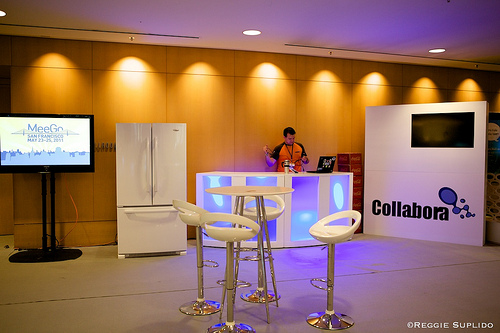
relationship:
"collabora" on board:
[368, 195, 453, 224] [360, 99, 489, 250]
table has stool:
[198, 180, 304, 328] [304, 210, 361, 329]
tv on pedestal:
[2, 109, 97, 176] [9, 169, 84, 265]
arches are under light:
[9, 36, 470, 109] [241, 28, 262, 39]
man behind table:
[258, 123, 313, 175] [198, 180, 304, 328]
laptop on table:
[309, 152, 338, 175] [198, 180, 304, 328]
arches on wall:
[0, 30, 500, 115] [9, 40, 392, 121]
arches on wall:
[0, 30, 500, 115] [24, 39, 301, 130]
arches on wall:
[0, 30, 500, 115] [34, 37, 356, 132]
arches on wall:
[0, 30, 500, 115] [8, 34, 274, 120]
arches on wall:
[0, 30, 500, 115] [134, 45, 432, 132]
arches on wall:
[0, 30, 500, 115] [231, 49, 456, 129]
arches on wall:
[0, 30, 500, 115] [275, 44, 488, 115]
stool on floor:
[300, 204, 360, 331] [111, 283, 421, 328]